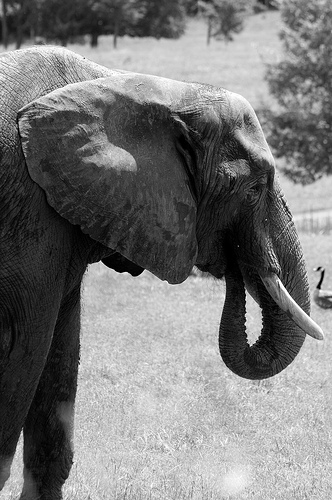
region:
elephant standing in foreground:
[4, 44, 321, 499]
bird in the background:
[312, 264, 330, 310]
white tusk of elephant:
[253, 268, 322, 341]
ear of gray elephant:
[17, 85, 199, 288]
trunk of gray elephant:
[211, 233, 305, 380]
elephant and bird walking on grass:
[4, 42, 326, 488]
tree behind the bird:
[261, 3, 330, 224]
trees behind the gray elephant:
[5, 2, 246, 45]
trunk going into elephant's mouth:
[205, 244, 293, 384]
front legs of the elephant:
[1, 268, 83, 497]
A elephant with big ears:
[16, 70, 241, 284]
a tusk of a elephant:
[249, 268, 327, 343]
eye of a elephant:
[248, 172, 269, 202]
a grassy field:
[106, 363, 180, 475]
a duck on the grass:
[299, 256, 328, 324]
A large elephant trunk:
[211, 244, 315, 391]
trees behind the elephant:
[7, 1, 268, 54]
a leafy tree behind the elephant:
[246, 7, 329, 182]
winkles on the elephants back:
[6, 47, 73, 98]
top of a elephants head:
[132, 87, 274, 192]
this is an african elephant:
[2, 40, 328, 496]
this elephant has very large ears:
[19, 78, 202, 293]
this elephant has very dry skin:
[3, 39, 328, 492]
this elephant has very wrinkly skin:
[3, 40, 321, 499]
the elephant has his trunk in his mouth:
[210, 219, 314, 394]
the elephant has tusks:
[242, 259, 328, 352]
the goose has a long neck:
[313, 259, 331, 315]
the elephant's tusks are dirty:
[242, 261, 327, 358]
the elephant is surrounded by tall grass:
[0, 218, 330, 497]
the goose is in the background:
[306, 259, 331, 318]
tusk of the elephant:
[258, 271, 328, 347]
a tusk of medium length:
[252, 261, 328, 342]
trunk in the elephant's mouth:
[203, 223, 313, 383]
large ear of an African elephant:
[16, 69, 194, 294]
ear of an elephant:
[13, 79, 200, 295]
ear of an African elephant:
[16, 83, 194, 276]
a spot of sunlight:
[199, 154, 253, 185]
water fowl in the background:
[305, 252, 330, 308]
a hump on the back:
[4, 40, 91, 65]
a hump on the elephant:
[6, 37, 92, 65]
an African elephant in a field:
[13, 5, 295, 457]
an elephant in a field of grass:
[8, 18, 320, 426]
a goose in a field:
[300, 254, 331, 319]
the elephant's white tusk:
[261, 265, 331, 337]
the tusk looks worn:
[253, 263, 330, 343]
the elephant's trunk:
[210, 216, 331, 404]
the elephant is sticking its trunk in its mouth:
[116, 67, 331, 391]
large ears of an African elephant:
[25, 83, 204, 300]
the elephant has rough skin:
[2, 46, 318, 498]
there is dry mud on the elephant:
[47, 90, 216, 277]